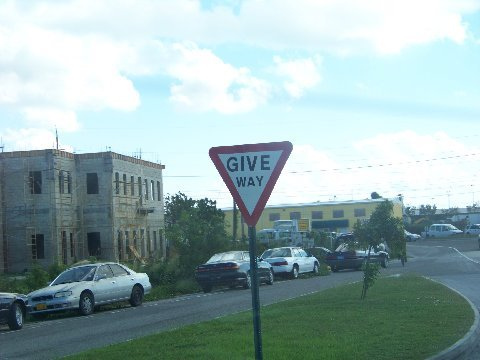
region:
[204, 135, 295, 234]
red white and black sign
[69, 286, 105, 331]
black tire and silver hubcap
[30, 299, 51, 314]
yellow license plate on car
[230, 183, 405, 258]
a large yellow building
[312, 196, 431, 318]
a small green tree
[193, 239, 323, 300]
black and white cars parked on road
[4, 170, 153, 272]
scaffold on side of building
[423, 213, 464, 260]
white van parked on road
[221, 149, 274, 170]
black letters that spell give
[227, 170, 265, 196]
black letters that spell way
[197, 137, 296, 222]
Give way on a sign.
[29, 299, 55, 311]
License plate on a car.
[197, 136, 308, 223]
Sign is a triangle.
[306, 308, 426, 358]
The grass is green.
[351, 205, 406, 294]
Tree in the grass.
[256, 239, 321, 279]
The car is white.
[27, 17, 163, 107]
Clouds in the sky.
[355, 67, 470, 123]
The sky is blue.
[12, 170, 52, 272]
Staircase on the side of the building.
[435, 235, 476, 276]
White line on the road.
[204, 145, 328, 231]
red and white triangular sign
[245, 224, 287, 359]
green metal sign post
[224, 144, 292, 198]
give way spelled out in black letters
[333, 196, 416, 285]
green tree in middle of road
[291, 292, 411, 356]
green grass in center median of road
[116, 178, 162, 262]
yellow metal scaffolding on side of building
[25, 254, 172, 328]
silver four door car on left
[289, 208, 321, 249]
yellow sign with black lettering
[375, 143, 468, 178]
wires in the sky over the roadway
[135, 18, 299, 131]
white fluffy clouds in blue sky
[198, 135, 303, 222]
The sign is triangular.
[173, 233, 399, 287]
Cars parked on the road.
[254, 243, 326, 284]
The car is white.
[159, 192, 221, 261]
The tree is green.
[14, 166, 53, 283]
Staircase on the side of the building.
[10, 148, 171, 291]
The building is brick.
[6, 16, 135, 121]
Clouds in the sky.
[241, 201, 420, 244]
The building is yellow.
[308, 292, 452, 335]
The grass is green.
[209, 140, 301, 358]
a sign in the grass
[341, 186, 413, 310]
a small tree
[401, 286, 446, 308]
flowers on the grass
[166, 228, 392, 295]
cars parked on side of road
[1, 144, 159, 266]
an old brick building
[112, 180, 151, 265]
scaffolding for the building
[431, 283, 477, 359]
the curb for the island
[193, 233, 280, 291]
a blue parked car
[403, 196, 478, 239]
cars in the parking lot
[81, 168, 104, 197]
A hole without a window